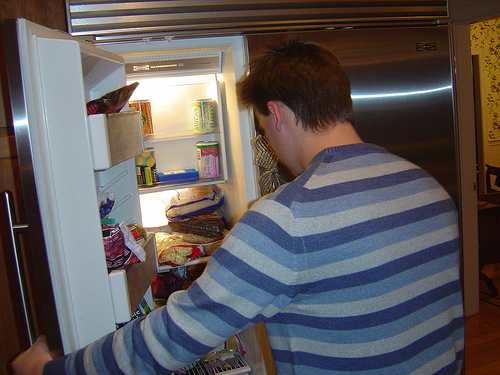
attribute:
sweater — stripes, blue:
[236, 163, 449, 371]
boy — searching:
[224, 59, 465, 358]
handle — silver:
[3, 191, 57, 347]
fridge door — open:
[1, 13, 178, 369]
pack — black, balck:
[87, 66, 155, 116]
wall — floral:
[471, 25, 494, 147]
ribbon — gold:
[252, 135, 290, 200]